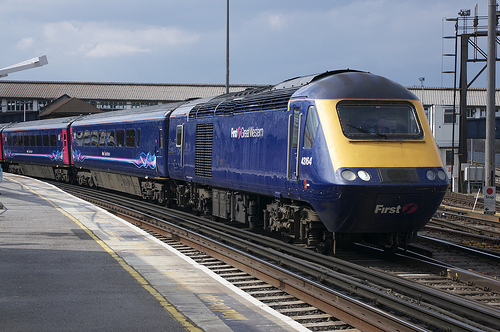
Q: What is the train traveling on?
A: Tracks.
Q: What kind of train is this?
A: Passenger.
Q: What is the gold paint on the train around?
A: Windshield.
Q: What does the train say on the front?
A: First.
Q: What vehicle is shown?
A: Train.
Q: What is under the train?
A: Tracks.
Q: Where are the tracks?
A: Under the train.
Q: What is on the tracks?
A: A train.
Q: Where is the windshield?
A: On the train.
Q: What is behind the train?
A: Buildings.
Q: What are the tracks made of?
A: Metal.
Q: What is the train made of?
A: Metal.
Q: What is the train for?
A: Transportation.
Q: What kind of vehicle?
A: Train.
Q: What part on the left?
A: Platform.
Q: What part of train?
A: Front.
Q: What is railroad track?
A: Steel.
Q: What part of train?
A: Bus.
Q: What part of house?
A: Roof.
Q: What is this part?
A: Railway line.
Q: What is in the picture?
A: Train.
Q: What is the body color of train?
A: Blue.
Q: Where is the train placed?
A: In the middle track.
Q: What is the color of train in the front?
A: Yellow.